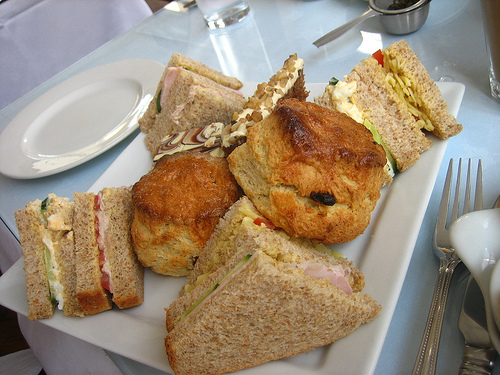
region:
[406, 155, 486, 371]
silver metal fork on table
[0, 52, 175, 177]
round white plate on table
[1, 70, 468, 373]
white rectangular plate on table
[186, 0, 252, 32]
clear drinking glass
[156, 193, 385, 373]
quarter of sandwich on white plate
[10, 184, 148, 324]
quarter of sandwich on white plate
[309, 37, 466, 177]
quarter of sandwich on white plate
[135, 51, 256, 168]
quarter of sandwich on white plate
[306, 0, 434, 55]
silver metal scoop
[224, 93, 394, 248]
round baked biscuit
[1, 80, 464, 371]
square white plate on table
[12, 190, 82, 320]
triangle shaped sandwich on plate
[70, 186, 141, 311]
cut sandwich next to sandwich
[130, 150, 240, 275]
biscuit next to cut sandwich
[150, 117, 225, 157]
marbled dessert next to biscuit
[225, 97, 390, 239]
tilted biscuit next to biscuit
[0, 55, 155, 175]
round ceramic plate next to square plate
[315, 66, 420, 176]
cut sandwich behind tilted biscuit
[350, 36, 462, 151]
sandwich on plate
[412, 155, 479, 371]
silver fork next to square plate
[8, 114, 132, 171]
the plate is empty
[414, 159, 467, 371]
the utensil is a fork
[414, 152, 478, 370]
the fork is silver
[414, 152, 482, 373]
fork is on table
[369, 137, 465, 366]
fork is beside the plate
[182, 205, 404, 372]
sandwiches on the plate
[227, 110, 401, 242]
biscuit on the plate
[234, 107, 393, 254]
the biscuit is brown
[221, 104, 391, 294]
biscuit is on sandwiches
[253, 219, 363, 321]
meat is on the sandwich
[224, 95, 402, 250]
golden puff pastry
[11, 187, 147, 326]
part of sandwich on wheat bread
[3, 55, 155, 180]
empty white plate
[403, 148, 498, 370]
fork resting on table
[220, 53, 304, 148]
piece of carrot cake with pecan topping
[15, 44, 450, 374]
plate with a lot of food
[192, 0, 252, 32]
part of a glass of water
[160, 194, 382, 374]
ham sandwich with lettuce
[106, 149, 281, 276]
pastry on plate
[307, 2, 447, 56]
steel container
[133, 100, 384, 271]
two biscuits in the center of the plate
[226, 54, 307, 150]
a slice of carrot cake with cream cheese frosting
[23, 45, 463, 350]
quartered sandwiches on a square plate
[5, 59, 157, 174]
empty white round plate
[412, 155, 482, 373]
a silver fork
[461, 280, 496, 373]
a silver knive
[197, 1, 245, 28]
the bottom of a water glass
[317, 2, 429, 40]
a silver tea infuser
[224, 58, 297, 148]
nuts on top of the cake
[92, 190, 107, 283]
a slice of tomato on the sandwich on the left